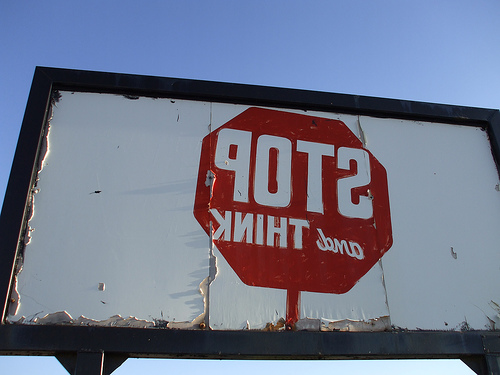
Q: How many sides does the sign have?
A: 8.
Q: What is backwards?
A: The sign.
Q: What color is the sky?
A: Blue.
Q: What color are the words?
A: White.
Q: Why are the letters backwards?
A: To see in mirror.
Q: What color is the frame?
A: Black.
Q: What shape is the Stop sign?
A: Octagon.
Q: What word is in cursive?
A: And.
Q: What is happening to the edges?
A: Peeling.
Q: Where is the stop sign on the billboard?
A: Middle.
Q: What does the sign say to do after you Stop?
A: Think.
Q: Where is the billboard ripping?
A: Seams.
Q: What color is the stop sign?
A: Red.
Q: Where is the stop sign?
A: On the billboard.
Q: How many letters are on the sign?
A: 12.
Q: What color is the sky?
A: Blue.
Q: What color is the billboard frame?
A: Black.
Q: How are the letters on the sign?
A: Backward.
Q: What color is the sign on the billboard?
A: Red.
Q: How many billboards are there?
A: 1.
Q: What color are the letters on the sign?
A: White.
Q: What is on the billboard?
A: A painting of a Stop sign.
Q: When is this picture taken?
A: During the day.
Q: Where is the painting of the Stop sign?
A: In the middle of the billboard.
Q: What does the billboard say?
A: "Stop and Think.".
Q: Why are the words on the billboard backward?
A: To grab someone's attention.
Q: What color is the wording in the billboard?
A: White.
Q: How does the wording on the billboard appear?
A: Backwards.